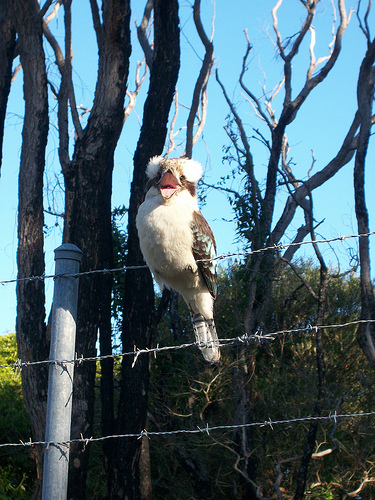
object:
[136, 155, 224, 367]
bird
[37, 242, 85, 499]
pole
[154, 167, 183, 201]
beak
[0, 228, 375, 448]
fence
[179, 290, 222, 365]
tail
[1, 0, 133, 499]
tree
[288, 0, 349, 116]
branch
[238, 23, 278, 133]
branch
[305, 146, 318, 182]
branch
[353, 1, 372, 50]
branch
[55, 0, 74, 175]
branch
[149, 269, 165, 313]
feather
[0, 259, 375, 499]
shrubbery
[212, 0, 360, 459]
tree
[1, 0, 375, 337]
sky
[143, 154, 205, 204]
head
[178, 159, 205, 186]
feathers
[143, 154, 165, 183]
feathers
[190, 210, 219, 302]
feathers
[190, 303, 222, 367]
feathers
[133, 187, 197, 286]
feathers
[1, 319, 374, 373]
barbed wire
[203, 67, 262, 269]
tree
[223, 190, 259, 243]
leaves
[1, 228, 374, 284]
barbed wire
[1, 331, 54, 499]
tree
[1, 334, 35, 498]
leaves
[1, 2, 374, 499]
forest